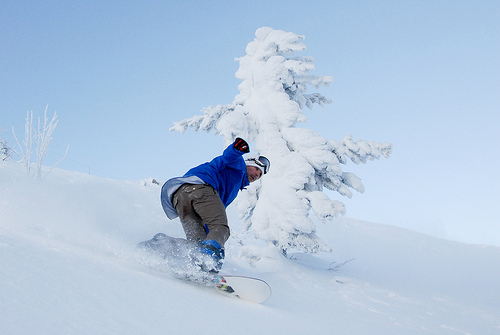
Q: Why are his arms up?
A: Balance.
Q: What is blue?
A: Coat.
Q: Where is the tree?
A: Beside him.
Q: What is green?
A: Pants.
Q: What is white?
A: Snow.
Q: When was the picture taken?
A: Daytime.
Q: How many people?
A: One.